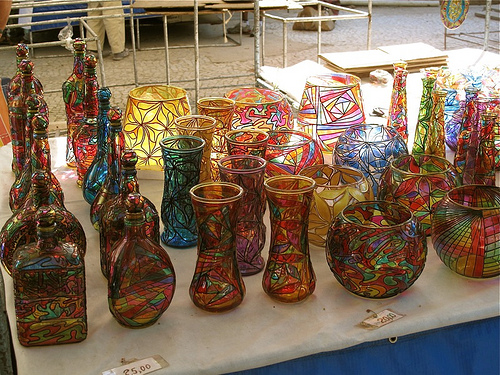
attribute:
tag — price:
[356, 307, 407, 330]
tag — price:
[101, 352, 168, 373]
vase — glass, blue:
[273, 168, 328, 303]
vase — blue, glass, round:
[243, 165, 345, 316]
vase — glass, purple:
[188, 179, 248, 311]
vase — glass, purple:
[160, 135, 201, 249]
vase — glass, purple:
[218, 150, 263, 272]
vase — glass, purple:
[268, 177, 314, 304]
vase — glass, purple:
[227, 123, 272, 215]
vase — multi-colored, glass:
[10, 201, 93, 351]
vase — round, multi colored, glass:
[426, 183, 497, 280]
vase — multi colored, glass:
[260, 172, 318, 301]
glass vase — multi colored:
[187, 176, 254, 329]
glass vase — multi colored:
[263, 173, 315, 321]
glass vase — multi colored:
[99, 206, 181, 331]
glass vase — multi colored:
[2, 206, 91, 366]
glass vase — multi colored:
[95, 122, 157, 271]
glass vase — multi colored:
[110, 193, 175, 330]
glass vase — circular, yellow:
[125, 76, 189, 160]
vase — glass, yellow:
[126, 85, 198, 170]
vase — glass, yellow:
[269, 175, 310, 297]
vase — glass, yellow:
[327, 199, 429, 296]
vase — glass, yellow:
[115, 208, 175, 328]